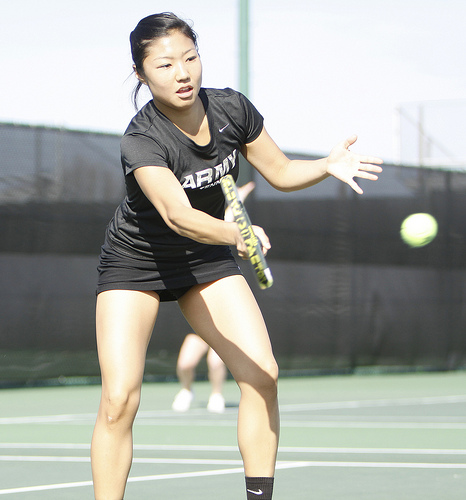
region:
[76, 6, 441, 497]
Person ready to hit tennis ball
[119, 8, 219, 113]
Girl with dark hair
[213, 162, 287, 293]
Hand holding tennis racket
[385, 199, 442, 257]
Tennis ball in the air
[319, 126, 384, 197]
Someone's left hand open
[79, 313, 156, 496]
Someone's right leg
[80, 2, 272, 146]
Woman wearing shirt with sports logo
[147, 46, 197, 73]
Eyes of a person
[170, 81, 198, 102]
Mouth of a person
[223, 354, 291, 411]
Knee of a person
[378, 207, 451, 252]
Green colored tennis ball in the air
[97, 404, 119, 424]
Scar on right knee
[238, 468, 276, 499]
Black sock with Nike logo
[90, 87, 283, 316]
Black tennis uniform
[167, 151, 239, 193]
Black shirt with white Army logo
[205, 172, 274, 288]
Tennis racket in a womans hand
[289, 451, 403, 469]
White line on tennis court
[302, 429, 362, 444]
Green pavement on tennis court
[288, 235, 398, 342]
Black screen around tennis court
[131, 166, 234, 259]
Right arm muscles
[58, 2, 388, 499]
Asian female tennis player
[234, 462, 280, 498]
black Nike brand tennis sock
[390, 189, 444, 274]
green tennis ball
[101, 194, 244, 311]
short black tennis skirt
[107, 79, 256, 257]
short sleeve black tennis shirt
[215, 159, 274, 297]
yellow and black tennis racket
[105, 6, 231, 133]
Face of female tennis player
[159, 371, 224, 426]
white tennis shoes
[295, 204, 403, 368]
black mesh court fence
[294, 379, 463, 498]
green and white tennis court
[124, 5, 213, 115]
the head of a woman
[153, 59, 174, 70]
the eye of a woman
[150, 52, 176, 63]
the eyebrow of the woman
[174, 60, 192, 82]
the nose of the woman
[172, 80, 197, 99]
the mouth of the woman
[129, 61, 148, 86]
the ear of the woman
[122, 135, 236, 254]
the arm of the woman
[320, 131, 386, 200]
the hand of the woman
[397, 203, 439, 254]
a ball in the air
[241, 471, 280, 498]
a black and white sock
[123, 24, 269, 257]
The woman is asian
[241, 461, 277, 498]
She is wearing black nike socks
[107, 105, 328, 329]
She has on a tshir and skort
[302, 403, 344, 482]
The court is white and green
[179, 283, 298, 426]
There is a shadow on her leg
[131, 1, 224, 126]
Her hair is dark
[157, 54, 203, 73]
She has brown eyes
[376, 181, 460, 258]
The ball is in the air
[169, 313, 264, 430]
A woman is standing in the background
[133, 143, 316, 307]
She is holding a tennis racket